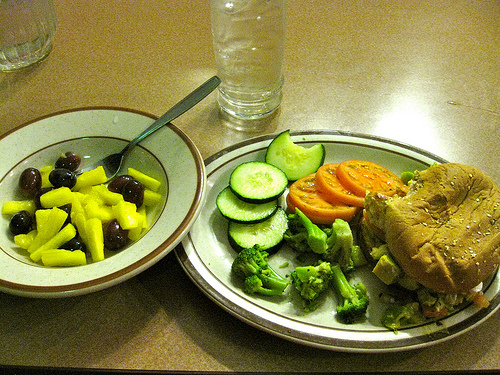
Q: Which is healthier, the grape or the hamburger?
A: The grape is healthier than the hamburger.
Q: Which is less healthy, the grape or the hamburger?
A: The hamburger is less healthy than the grape.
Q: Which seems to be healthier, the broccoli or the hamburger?
A: The broccoli is healthier than the hamburger.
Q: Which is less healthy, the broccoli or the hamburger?
A: The hamburger is less healthy than the broccoli.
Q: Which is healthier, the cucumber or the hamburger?
A: The cucumber is healthier than the hamburger.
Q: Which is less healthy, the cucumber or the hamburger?
A: The hamburger is less healthy than the cucumber.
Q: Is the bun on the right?
A: Yes, the bun is on the right of the image.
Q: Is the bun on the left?
A: No, the bun is on the right of the image.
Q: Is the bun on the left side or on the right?
A: The bun is on the right of the image.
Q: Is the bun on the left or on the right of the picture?
A: The bun is on the right of the image.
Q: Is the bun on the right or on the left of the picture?
A: The bun is on the right of the image.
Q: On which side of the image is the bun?
A: The bun is on the right of the image.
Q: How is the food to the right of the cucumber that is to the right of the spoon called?
A: The food is a bun.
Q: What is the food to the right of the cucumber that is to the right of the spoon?
A: The food is a bun.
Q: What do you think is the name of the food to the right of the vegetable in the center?
A: The food is a bun.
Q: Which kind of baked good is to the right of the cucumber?
A: The food is a bun.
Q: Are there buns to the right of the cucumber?
A: Yes, there is a bun to the right of the cucumber.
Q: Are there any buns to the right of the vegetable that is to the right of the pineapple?
A: Yes, there is a bun to the right of the cucumber.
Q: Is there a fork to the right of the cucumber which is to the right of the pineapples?
A: No, there is a bun to the right of the cucumber.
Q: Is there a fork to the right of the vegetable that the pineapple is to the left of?
A: No, there is a bun to the right of the cucumber.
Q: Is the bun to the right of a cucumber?
A: Yes, the bun is to the right of a cucumber.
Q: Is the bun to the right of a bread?
A: No, the bun is to the right of a cucumber.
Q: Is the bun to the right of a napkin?
A: No, the bun is to the right of the tomato.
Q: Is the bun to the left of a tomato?
A: No, the bun is to the right of a tomato.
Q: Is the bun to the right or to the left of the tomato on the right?
A: The bun is to the right of the tomato.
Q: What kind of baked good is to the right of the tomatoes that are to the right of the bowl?
A: The food is a bun.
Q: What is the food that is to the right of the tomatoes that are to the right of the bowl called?
A: The food is a bun.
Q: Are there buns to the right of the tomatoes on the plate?
A: Yes, there is a bun to the right of the tomatoes.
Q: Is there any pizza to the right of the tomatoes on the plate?
A: No, there is a bun to the right of the tomatoes.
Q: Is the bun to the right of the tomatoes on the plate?
A: Yes, the bun is to the right of the tomatoes.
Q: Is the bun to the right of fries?
A: No, the bun is to the right of the tomatoes.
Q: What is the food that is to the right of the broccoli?
A: The food is a bun.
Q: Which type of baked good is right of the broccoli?
A: The food is a bun.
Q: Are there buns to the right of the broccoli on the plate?
A: Yes, there is a bun to the right of the broccoli.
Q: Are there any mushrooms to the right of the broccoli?
A: No, there is a bun to the right of the broccoli.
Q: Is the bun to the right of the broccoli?
A: Yes, the bun is to the right of the broccoli.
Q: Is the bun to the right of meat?
A: No, the bun is to the right of the broccoli.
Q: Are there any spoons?
A: Yes, there is a spoon.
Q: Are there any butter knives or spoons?
A: Yes, there is a spoon.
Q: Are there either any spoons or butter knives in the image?
A: Yes, there is a spoon.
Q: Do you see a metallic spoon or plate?
A: Yes, there is a metal spoon.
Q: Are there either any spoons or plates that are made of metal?
A: Yes, the spoon is made of metal.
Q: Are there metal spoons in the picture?
A: Yes, there is a metal spoon.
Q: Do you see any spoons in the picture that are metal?
A: Yes, there is a metal spoon.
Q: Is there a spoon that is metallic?
A: Yes, there is a spoon that is metallic.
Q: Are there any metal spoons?
A: Yes, there is a spoon that is made of metal.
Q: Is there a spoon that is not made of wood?
A: Yes, there is a spoon that is made of metal.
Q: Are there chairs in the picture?
A: No, there are no chairs.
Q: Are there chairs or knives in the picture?
A: No, there are no chairs or knives.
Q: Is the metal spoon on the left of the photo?
A: Yes, the spoon is on the left of the image.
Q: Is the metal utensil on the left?
A: Yes, the spoon is on the left of the image.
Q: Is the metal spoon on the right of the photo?
A: No, the spoon is on the left of the image.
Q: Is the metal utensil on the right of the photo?
A: No, the spoon is on the left of the image.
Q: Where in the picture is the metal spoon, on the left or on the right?
A: The spoon is on the left of the image.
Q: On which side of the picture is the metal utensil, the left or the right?
A: The spoon is on the left of the image.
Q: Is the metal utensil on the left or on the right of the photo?
A: The spoon is on the left of the image.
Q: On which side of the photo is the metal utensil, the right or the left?
A: The spoon is on the left of the image.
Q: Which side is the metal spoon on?
A: The spoon is on the left of the image.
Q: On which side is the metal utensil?
A: The spoon is on the left of the image.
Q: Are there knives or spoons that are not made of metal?
A: No, there is a spoon but it is made of metal.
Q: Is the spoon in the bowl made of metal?
A: Yes, the spoon is made of metal.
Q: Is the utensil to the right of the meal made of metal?
A: Yes, the spoon is made of metal.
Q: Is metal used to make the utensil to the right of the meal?
A: Yes, the spoon is made of metal.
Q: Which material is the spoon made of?
A: The spoon is made of metal.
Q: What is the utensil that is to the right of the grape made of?
A: The spoon is made of metal.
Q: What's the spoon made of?
A: The spoon is made of metal.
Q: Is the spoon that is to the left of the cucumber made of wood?
A: No, the spoon is made of metal.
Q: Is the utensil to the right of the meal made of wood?
A: No, the spoon is made of metal.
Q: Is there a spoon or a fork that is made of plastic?
A: No, there is a spoon but it is made of metal.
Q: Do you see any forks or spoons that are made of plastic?
A: No, there is a spoon but it is made of metal.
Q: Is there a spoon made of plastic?
A: No, there is a spoon but it is made of metal.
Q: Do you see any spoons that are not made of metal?
A: No, there is a spoon but it is made of metal.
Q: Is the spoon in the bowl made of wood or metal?
A: The spoon is made of metal.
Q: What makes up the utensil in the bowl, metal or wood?
A: The spoon is made of metal.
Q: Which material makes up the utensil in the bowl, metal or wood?
A: The spoon is made of metal.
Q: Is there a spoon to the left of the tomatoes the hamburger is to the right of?
A: Yes, there is a spoon to the left of the tomatoes.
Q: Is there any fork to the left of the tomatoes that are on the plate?
A: No, there is a spoon to the left of the tomatoes.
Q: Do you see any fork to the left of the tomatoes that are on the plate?
A: No, there is a spoon to the left of the tomatoes.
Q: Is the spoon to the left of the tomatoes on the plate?
A: Yes, the spoon is to the left of the tomatoes.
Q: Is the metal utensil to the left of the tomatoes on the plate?
A: Yes, the spoon is to the left of the tomatoes.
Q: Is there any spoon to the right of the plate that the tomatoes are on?
A: No, the spoon is to the left of the plate.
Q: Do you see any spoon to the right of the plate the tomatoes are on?
A: No, the spoon is to the left of the plate.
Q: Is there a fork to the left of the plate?
A: No, there is a spoon to the left of the plate.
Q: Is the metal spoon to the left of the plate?
A: Yes, the spoon is to the left of the plate.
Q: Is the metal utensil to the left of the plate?
A: Yes, the spoon is to the left of the plate.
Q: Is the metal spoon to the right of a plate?
A: No, the spoon is to the left of a plate.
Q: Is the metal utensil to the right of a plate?
A: No, the spoon is to the left of a plate.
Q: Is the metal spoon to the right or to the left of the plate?
A: The spoon is to the left of the plate.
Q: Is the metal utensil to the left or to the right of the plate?
A: The spoon is to the left of the plate.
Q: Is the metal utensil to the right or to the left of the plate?
A: The spoon is to the left of the plate.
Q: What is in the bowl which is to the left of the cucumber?
A: The spoon is in the bowl.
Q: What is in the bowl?
A: The spoon is in the bowl.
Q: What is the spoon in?
A: The spoon is in the bowl.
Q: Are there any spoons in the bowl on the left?
A: Yes, there is a spoon in the bowl.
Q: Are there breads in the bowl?
A: No, there is a spoon in the bowl.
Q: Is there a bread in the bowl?
A: No, there is a spoon in the bowl.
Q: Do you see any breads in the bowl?
A: No, there is a spoon in the bowl.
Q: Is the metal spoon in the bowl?
A: Yes, the spoon is in the bowl.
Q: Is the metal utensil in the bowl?
A: Yes, the spoon is in the bowl.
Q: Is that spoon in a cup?
A: No, the spoon is in the bowl.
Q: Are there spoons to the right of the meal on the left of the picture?
A: Yes, there is a spoon to the right of the meal.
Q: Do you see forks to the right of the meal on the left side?
A: No, there is a spoon to the right of the meal.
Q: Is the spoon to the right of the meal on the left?
A: Yes, the spoon is to the right of the meal.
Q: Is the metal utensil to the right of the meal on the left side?
A: Yes, the spoon is to the right of the meal.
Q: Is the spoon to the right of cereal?
A: No, the spoon is to the right of the meal.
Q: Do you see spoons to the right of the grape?
A: Yes, there is a spoon to the right of the grape.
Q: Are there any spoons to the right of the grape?
A: Yes, there is a spoon to the right of the grape.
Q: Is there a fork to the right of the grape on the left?
A: No, there is a spoon to the right of the grape.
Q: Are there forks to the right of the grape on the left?
A: No, there is a spoon to the right of the grape.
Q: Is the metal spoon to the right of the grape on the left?
A: Yes, the spoon is to the right of the grape.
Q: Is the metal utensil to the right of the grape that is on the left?
A: Yes, the spoon is to the right of the grape.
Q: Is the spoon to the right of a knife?
A: No, the spoon is to the right of the grape.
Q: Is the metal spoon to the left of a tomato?
A: Yes, the spoon is to the left of a tomato.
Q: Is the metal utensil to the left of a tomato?
A: Yes, the spoon is to the left of a tomato.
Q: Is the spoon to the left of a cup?
A: No, the spoon is to the left of a tomato.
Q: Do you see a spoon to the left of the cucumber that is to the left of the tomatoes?
A: Yes, there is a spoon to the left of the cucumber.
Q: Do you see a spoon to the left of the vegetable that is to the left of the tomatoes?
A: Yes, there is a spoon to the left of the cucumber.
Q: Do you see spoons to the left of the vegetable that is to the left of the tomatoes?
A: Yes, there is a spoon to the left of the cucumber.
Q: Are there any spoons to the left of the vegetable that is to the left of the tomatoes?
A: Yes, there is a spoon to the left of the cucumber.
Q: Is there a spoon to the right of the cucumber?
A: No, the spoon is to the left of the cucumber.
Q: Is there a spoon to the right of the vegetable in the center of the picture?
A: No, the spoon is to the left of the cucumber.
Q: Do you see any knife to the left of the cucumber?
A: No, there is a spoon to the left of the cucumber.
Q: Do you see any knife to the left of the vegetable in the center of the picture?
A: No, there is a spoon to the left of the cucumber.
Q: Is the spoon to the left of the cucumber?
A: Yes, the spoon is to the left of the cucumber.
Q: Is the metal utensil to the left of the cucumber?
A: Yes, the spoon is to the left of the cucumber.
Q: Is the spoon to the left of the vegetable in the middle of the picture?
A: Yes, the spoon is to the left of the cucumber.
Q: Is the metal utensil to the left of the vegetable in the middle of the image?
A: Yes, the spoon is to the left of the cucumber.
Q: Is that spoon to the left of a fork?
A: No, the spoon is to the left of the cucumber.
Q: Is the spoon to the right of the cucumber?
A: No, the spoon is to the left of the cucumber.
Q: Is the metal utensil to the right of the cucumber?
A: No, the spoon is to the left of the cucumber.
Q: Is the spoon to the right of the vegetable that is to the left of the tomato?
A: No, the spoon is to the left of the cucumber.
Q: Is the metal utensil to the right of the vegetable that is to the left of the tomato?
A: No, the spoon is to the left of the cucumber.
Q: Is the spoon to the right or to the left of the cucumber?
A: The spoon is to the left of the cucumber.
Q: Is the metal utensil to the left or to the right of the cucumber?
A: The spoon is to the left of the cucumber.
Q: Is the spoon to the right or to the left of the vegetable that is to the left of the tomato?
A: The spoon is to the left of the cucumber.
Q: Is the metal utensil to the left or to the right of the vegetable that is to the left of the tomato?
A: The spoon is to the left of the cucumber.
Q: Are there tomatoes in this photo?
A: Yes, there is a tomato.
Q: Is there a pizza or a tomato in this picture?
A: Yes, there is a tomato.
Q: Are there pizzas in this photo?
A: No, there are no pizzas.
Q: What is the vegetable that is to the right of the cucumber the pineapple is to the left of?
A: The vegetable is a tomato.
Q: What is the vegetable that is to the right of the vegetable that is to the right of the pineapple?
A: The vegetable is a tomato.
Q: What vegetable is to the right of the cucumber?
A: The vegetable is a tomato.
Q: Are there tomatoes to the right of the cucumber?
A: Yes, there is a tomato to the right of the cucumber.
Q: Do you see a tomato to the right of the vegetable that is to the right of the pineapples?
A: Yes, there is a tomato to the right of the cucumber.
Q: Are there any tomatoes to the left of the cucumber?
A: No, the tomato is to the right of the cucumber.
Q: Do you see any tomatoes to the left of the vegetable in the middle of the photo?
A: No, the tomato is to the right of the cucumber.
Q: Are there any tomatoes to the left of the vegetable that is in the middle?
A: No, the tomato is to the right of the cucumber.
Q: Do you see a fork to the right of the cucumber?
A: No, there is a tomato to the right of the cucumber.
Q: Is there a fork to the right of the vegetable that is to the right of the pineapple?
A: No, there is a tomato to the right of the cucumber.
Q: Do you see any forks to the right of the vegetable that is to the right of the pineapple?
A: No, there is a tomato to the right of the cucumber.